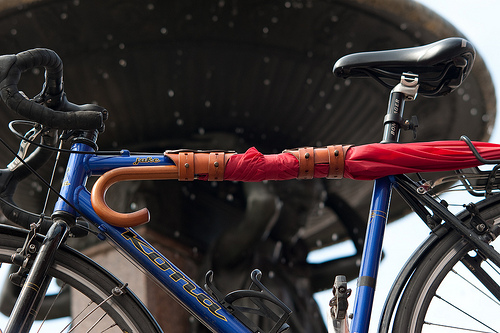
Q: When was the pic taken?
A: During the day.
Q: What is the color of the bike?
A: Blue.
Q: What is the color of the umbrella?
A: Orange.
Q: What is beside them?
A: The road.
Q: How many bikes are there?
A: 1.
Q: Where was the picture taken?
A: Close to a statue.